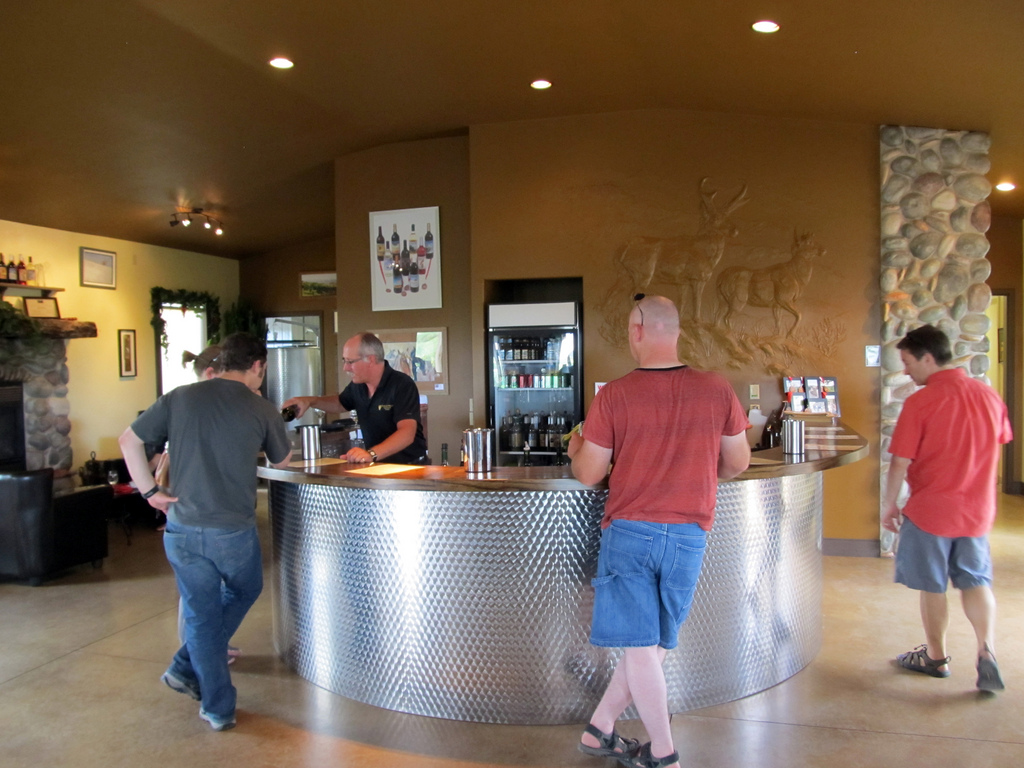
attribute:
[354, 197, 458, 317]
artwork — framed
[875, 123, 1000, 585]
wall — rocks, stone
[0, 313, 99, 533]
fireplace — stone, brick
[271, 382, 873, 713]
bar — horseshoe shaped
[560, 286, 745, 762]
man — bald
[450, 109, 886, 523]
wall — brown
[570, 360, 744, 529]
shirt — red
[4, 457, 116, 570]
chair — black